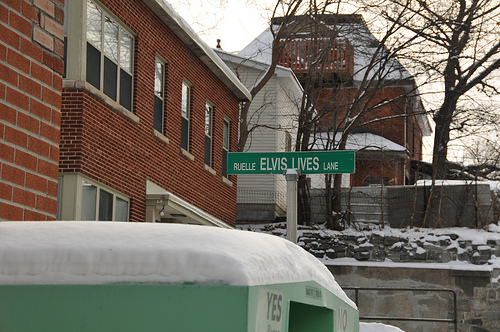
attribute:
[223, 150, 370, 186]
sign is green — street, Elvis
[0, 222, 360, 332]
there is a structure — green, roof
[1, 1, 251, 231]
there is a building — red, brick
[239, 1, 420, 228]
there is a tree — covered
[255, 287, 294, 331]
there is a sign — printed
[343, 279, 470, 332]
railing is metal — black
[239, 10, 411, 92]
roof has snow — covered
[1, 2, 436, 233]
three buildings — talll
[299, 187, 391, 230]
snow on railing — covered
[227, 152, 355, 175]
elvis sign. — rectangular